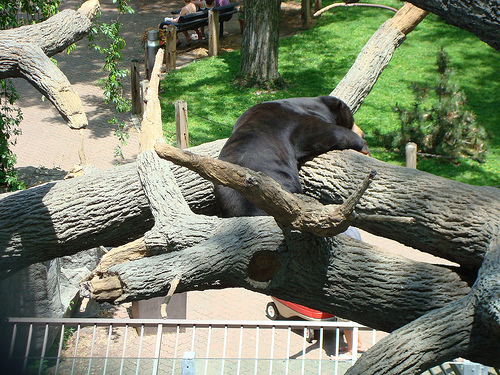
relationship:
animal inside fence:
[213, 93, 367, 223] [8, 313, 499, 371]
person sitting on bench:
[178, 4, 201, 44] [146, 9, 240, 54]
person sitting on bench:
[203, 2, 220, 28] [146, 9, 240, 54]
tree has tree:
[227, 0, 287, 92] [232, 0, 287, 92]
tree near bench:
[227, 0, 287, 92] [141, 2, 238, 73]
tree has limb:
[0, 0, 499, 374] [87, 46, 475, 373]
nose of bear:
[342, 109, 367, 146] [202, 87, 394, 234]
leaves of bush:
[379, 78, 431, 124] [380, 43, 488, 167]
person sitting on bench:
[158, 0, 198, 46] [156, 5, 238, 49]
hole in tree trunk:
[245, 246, 285, 283] [78, 206, 483, 366]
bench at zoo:
[150, 2, 227, 34] [36, 22, 438, 314]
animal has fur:
[213, 93, 367, 223] [215, 94, 345, 216]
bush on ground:
[395, 43, 489, 170] [120, 4, 485, 187]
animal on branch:
[207, 92, 371, 223] [1, 130, 497, 292]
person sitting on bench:
[158, 0, 198, 46] [160, 2, 275, 64]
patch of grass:
[276, 21, 363, 68] [290, 45, 324, 70]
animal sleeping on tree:
[213, 93, 367, 223] [24, 137, 489, 285]